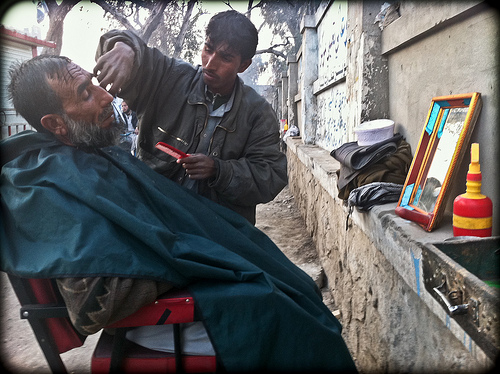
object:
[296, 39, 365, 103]
wall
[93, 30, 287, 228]
gray jacket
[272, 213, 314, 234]
ground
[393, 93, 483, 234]
mirror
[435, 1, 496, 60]
wall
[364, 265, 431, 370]
wall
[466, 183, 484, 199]
yellow stripes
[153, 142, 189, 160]
red comb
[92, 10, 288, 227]
barber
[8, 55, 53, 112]
gray hair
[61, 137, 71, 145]
neck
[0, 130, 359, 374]
blanket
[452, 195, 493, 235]
stripes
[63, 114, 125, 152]
beard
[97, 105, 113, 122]
mustache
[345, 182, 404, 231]
sheet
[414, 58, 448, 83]
wall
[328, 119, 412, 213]
clothes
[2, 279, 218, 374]
barber chair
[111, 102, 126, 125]
silver scissors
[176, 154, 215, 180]
hand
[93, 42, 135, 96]
hand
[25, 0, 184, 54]
trees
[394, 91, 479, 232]
frame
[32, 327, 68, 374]
metal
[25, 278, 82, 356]
cushion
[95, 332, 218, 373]
cushion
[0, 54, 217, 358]
man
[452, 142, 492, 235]
bottle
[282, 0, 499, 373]
ledge